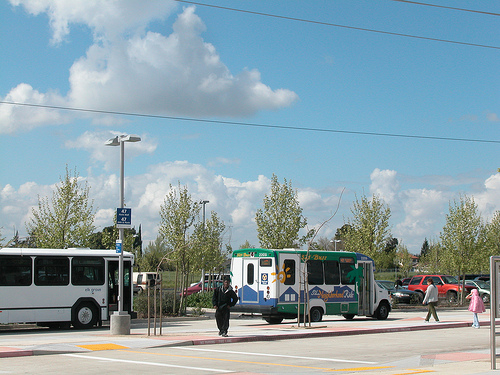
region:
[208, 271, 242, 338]
Man in black walking on the sidewalk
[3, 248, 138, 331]
A white bus driving by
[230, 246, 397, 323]
A short bus driving by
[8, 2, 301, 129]
Fluffy cloud in the sky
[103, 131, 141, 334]
A street lamp in the daytime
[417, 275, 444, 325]
A woman walking on the sidewalk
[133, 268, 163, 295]
The rear end of a parked van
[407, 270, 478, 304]
A red, parked SUV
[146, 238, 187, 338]
A dead tree supported by two beams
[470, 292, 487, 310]
Person wearing pink coat.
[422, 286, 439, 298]
Person wearing tan coat.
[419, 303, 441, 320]
Person wearing dark pants.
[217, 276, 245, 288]
Person has black hair.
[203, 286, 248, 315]
Person wearing dark coat.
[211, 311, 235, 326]
Person wearing black pants.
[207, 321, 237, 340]
Person walking on sidewalk.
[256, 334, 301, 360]
White line marking road.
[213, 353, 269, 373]
Yellow line marking road.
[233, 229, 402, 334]
green white and blue bus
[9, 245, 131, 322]
black and white bus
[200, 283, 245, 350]
person wearing black standing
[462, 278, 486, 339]
girl in pink dress on right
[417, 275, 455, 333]
person in white jacket on right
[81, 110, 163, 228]
white light post with a blue and white sign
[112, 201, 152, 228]
blue and white sign on light post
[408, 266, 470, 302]
red and black suv on right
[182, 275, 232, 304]
back end of burgundy car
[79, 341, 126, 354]
yellow paint markings on sidewalk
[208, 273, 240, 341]
man walking towards cross walk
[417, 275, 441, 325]
woman walking towards bus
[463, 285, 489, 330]
little girl with pink coat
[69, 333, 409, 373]
cross walk area on street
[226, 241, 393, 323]
parked small city bus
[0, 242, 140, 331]
large white city bus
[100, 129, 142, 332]
street lamp with bus signs on it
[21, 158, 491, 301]
young trees behind buses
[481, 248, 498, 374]
bus information sign on corner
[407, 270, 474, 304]
orange-red SUV behind woman walking to bus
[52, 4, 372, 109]
it is a cloud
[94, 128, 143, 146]
it is night lamp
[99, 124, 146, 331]
it is a lamp post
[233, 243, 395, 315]
it is a tempo van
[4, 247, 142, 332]
it is a white color bus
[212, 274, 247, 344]
man wearing black color dress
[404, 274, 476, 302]
it is a red color car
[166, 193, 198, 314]
it is a tree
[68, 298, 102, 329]
it is a bus tire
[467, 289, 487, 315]
woman wearing pink color sweater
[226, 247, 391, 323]
a green and white shuttle bus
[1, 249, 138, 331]
a white shuttle bus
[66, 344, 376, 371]
a marked pedestrian crosswalk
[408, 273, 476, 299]
a parked red SUV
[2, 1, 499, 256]
a cloudy blue sky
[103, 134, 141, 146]
a set of overhead parking lights